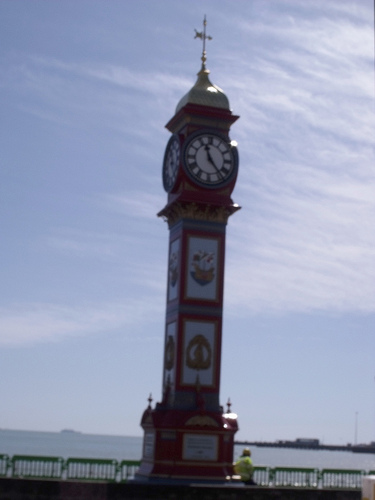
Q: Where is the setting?
A: Daytime near the ocean.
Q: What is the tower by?
A: It is by water.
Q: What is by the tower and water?
A: A fence.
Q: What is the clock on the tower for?
A: To tell time.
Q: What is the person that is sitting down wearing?
A: A yellow jacket.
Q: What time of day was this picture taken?
A: It was taken during daytime.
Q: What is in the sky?
A: Clouds are in the sky.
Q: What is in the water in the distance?
A: A boat.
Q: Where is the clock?
A: Near the top of the tower.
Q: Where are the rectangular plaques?
A: In the middle of the tower.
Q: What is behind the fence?
A: The ocean.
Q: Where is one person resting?
A: Near the base of the tower.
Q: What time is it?
A: 11:25.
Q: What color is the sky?
A: Blue.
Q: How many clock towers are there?
A: One.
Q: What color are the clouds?
A: White.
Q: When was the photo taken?
A: Daytime.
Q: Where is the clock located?
A: The top of the tower.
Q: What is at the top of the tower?
A: A clock.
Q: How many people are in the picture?
A: One.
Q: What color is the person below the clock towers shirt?
A: Yellow.